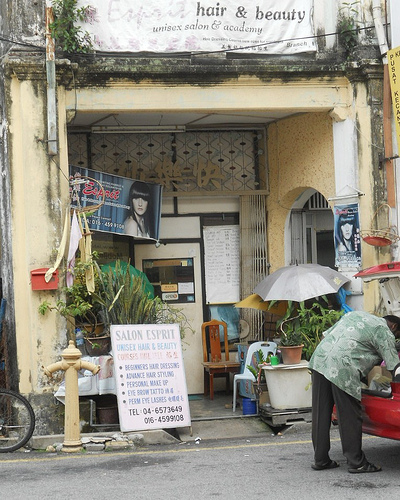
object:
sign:
[108, 322, 192, 433]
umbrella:
[231, 291, 301, 319]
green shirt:
[305, 311, 400, 401]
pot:
[276, 343, 304, 365]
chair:
[200, 318, 241, 400]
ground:
[65, 79, 352, 122]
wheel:
[68, 175, 105, 213]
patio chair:
[232, 340, 279, 413]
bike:
[0, 381, 36, 456]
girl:
[122, 181, 153, 239]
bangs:
[130, 182, 151, 200]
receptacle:
[29, 267, 59, 292]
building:
[0, 0, 398, 436]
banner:
[68, 163, 164, 248]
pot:
[83, 334, 112, 356]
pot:
[83, 321, 104, 336]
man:
[302, 308, 397, 472]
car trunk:
[330, 259, 400, 442]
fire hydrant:
[41, 337, 101, 454]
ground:
[0, 417, 400, 500]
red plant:
[279, 333, 302, 346]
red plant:
[36, 250, 111, 349]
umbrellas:
[251, 263, 353, 304]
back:
[201, 319, 230, 363]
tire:
[0, 389, 36, 454]